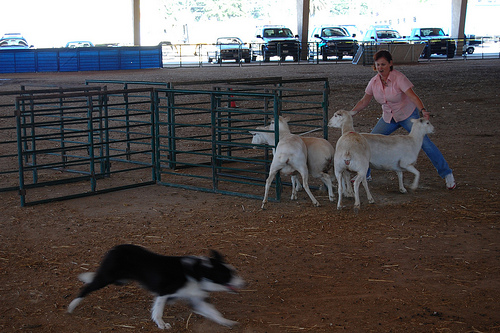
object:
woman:
[351, 49, 457, 190]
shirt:
[363, 71, 418, 123]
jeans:
[366, 111, 452, 177]